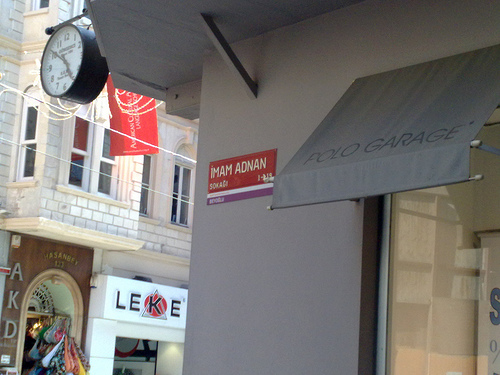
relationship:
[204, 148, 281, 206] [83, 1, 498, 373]
sign on building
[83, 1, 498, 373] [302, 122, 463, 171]
building has a logo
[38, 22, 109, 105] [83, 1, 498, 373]
clock on building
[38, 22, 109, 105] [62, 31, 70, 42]
clock has a number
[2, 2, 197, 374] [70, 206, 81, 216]
building has a stone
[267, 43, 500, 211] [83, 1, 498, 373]
canopy on building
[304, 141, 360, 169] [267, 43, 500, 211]
polo on sign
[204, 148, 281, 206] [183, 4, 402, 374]
sign on wall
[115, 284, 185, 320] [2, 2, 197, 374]
logo on building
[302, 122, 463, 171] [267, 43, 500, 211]
logo on canopy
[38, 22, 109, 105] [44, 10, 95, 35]
clock on pole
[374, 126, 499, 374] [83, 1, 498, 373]
window on building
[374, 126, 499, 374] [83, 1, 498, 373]
glass on building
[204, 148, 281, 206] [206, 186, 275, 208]
sign has line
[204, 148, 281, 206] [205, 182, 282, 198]
sign has a line